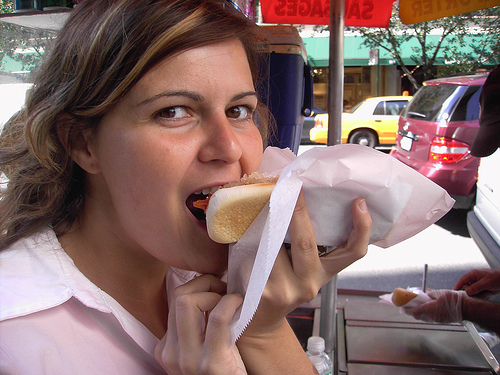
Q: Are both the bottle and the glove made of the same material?
A: Yes, both the bottle and the glove are made of plastic.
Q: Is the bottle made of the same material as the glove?
A: Yes, both the bottle and the glove are made of plastic.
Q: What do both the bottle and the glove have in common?
A: The material, both the bottle and the glove are plastic.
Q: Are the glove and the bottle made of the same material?
A: Yes, both the glove and the bottle are made of plastic.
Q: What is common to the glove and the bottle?
A: The material, both the glove and the bottle are plastic.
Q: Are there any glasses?
A: No, there are no glasses.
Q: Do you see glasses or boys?
A: No, there are no glasses or boys.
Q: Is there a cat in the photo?
A: No, there are no cats.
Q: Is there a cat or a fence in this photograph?
A: No, there are no cats or fences.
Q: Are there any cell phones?
A: No, there are no cell phones.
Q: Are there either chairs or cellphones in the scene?
A: No, there are no cellphones or chairs.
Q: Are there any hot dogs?
A: Yes, there is a hot dog.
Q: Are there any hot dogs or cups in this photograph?
A: Yes, there is a hot dog.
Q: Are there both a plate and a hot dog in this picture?
A: No, there is a hot dog but no plates.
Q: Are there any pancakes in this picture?
A: No, there are no pancakes.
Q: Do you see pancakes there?
A: No, there are no pancakes.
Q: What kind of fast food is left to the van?
A: The food is a hot dog.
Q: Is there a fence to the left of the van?
A: No, there is a hot dog to the left of the van.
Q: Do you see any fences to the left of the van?
A: No, there is a hot dog to the left of the van.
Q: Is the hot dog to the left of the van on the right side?
A: Yes, the hot dog is to the left of the van.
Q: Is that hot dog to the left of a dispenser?
A: No, the hot dog is to the left of the van.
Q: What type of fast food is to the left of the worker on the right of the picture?
A: The food is a hot dog.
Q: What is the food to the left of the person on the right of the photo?
A: The food is a hot dog.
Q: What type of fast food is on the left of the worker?
A: The food is a hot dog.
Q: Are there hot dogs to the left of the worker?
A: Yes, there is a hot dog to the left of the worker.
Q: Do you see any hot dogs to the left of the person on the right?
A: Yes, there is a hot dog to the left of the worker.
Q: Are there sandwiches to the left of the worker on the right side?
A: No, there is a hot dog to the left of the worker.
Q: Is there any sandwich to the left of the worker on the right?
A: No, there is a hot dog to the left of the worker.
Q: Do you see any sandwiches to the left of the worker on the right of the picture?
A: No, there is a hot dog to the left of the worker.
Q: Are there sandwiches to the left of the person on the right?
A: No, there is a hot dog to the left of the worker.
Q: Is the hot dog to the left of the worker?
A: Yes, the hot dog is to the left of the worker.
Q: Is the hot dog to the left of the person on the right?
A: Yes, the hot dog is to the left of the worker.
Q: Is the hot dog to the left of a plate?
A: No, the hot dog is to the left of the worker.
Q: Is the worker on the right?
A: Yes, the worker is on the right of the image.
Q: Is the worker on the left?
A: No, the worker is on the right of the image.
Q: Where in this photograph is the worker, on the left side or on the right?
A: The worker is on the right of the image.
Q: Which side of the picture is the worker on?
A: The worker is on the right of the image.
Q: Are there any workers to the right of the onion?
A: Yes, there is a worker to the right of the onion.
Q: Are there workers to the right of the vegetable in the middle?
A: Yes, there is a worker to the right of the onion.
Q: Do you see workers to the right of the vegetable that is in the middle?
A: Yes, there is a worker to the right of the onion.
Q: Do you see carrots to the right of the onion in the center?
A: No, there is a worker to the right of the onion.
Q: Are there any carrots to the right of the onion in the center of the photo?
A: No, there is a worker to the right of the onion.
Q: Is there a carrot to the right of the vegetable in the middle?
A: No, there is a worker to the right of the onion.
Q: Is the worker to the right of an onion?
A: Yes, the worker is to the right of an onion.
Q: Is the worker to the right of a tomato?
A: No, the worker is to the right of an onion.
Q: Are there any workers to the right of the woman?
A: Yes, there is a worker to the right of the woman.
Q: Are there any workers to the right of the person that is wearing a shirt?
A: Yes, there is a worker to the right of the woman.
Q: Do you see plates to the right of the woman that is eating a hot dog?
A: No, there is a worker to the right of the woman.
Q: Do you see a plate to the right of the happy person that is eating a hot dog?
A: No, there is a worker to the right of the woman.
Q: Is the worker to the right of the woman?
A: Yes, the worker is to the right of the woman.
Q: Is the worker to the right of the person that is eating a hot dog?
A: Yes, the worker is to the right of the woman.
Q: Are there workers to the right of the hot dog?
A: Yes, there is a worker to the right of the hot dog.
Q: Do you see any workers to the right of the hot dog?
A: Yes, there is a worker to the right of the hot dog.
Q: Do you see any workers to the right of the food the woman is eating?
A: Yes, there is a worker to the right of the hot dog.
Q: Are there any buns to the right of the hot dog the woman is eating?
A: No, there is a worker to the right of the hot dog.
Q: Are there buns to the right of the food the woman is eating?
A: No, there is a worker to the right of the hot dog.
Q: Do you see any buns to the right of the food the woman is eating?
A: No, there is a worker to the right of the hot dog.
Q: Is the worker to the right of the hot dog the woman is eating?
A: Yes, the worker is to the right of the hot dog.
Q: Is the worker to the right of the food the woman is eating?
A: Yes, the worker is to the right of the hot dog.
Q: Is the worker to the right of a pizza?
A: No, the worker is to the right of the hot dog.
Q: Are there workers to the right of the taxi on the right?
A: Yes, there is a worker to the right of the cab.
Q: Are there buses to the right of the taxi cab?
A: No, there is a worker to the right of the taxi cab.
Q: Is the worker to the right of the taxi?
A: Yes, the worker is to the right of the taxi.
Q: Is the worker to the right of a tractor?
A: No, the worker is to the right of the taxi.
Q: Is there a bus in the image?
A: No, there are no buses.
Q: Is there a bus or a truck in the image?
A: No, there are no buses or trucks.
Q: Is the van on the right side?
A: Yes, the van is on the right of the image.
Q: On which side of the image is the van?
A: The van is on the right of the image.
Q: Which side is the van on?
A: The van is on the right of the image.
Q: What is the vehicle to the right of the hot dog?
A: The vehicle is a van.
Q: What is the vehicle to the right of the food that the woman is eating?
A: The vehicle is a van.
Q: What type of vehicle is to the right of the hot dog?
A: The vehicle is a van.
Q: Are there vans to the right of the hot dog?
A: Yes, there is a van to the right of the hot dog.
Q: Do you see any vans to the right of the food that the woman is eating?
A: Yes, there is a van to the right of the hot dog.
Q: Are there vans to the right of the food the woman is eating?
A: Yes, there is a van to the right of the hot dog.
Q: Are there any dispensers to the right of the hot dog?
A: No, there is a van to the right of the hot dog.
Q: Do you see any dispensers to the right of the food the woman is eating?
A: No, there is a van to the right of the hot dog.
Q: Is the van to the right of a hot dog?
A: Yes, the van is to the right of a hot dog.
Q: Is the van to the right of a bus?
A: No, the van is to the right of a hot dog.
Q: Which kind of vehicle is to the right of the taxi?
A: The vehicle is a van.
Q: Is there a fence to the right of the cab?
A: No, there is a van to the right of the cab.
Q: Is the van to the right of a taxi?
A: Yes, the van is to the right of a taxi.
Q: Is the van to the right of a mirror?
A: No, the van is to the right of a taxi.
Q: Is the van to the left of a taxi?
A: No, the van is to the right of a taxi.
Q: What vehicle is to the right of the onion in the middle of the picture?
A: The vehicle is a van.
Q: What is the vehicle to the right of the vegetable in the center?
A: The vehicle is a van.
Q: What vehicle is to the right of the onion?
A: The vehicle is a van.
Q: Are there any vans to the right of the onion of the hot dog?
A: Yes, there is a van to the right of the onion.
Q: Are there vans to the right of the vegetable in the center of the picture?
A: Yes, there is a van to the right of the onion.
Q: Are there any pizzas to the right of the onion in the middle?
A: No, there is a van to the right of the onion.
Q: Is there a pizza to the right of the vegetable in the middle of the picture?
A: No, there is a van to the right of the onion.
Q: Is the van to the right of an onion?
A: Yes, the van is to the right of an onion.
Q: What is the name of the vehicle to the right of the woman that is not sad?
A: The vehicle is a van.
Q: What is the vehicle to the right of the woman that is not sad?
A: The vehicle is a van.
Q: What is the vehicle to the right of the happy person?
A: The vehicle is a van.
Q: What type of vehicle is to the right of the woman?
A: The vehicle is a van.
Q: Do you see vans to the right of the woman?
A: Yes, there is a van to the right of the woman.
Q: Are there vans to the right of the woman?
A: Yes, there is a van to the right of the woman.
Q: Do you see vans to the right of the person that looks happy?
A: Yes, there is a van to the right of the woman.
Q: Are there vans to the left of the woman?
A: No, the van is to the right of the woman.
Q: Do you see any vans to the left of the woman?
A: No, the van is to the right of the woman.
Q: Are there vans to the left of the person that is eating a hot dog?
A: No, the van is to the right of the woman.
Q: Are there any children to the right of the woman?
A: No, there is a van to the right of the woman.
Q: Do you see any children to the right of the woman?
A: No, there is a van to the right of the woman.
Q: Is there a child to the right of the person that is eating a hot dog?
A: No, there is a van to the right of the woman.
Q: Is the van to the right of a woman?
A: Yes, the van is to the right of a woman.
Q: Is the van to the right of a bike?
A: No, the van is to the right of a woman.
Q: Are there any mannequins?
A: No, there are no mannequins.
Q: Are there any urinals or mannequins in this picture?
A: No, there are no mannequins or urinals.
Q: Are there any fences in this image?
A: No, there are no fences.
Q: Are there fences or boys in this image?
A: No, there are no fences or boys.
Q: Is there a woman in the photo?
A: Yes, there is a woman.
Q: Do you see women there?
A: Yes, there is a woman.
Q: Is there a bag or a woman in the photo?
A: Yes, there is a woman.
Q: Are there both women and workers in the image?
A: Yes, there are both a woman and a worker.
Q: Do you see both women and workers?
A: Yes, there are both a woman and a worker.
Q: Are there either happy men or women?
A: Yes, there is a happy woman.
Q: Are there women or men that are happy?
A: Yes, the woman is happy.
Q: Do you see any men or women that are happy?
A: Yes, the woman is happy.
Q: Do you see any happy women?
A: Yes, there is a happy woman.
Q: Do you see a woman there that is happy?
A: Yes, there is a woman that is happy.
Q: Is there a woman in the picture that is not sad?
A: Yes, there is a happy woman.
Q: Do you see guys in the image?
A: No, there are no guys.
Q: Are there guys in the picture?
A: No, there are no guys.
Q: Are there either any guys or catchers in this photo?
A: No, there are no guys or catchers.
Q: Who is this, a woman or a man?
A: This is a woman.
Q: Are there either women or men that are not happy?
A: No, there is a woman but she is happy.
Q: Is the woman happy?
A: Yes, the woman is happy.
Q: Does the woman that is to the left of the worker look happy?
A: Yes, the woman is happy.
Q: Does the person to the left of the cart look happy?
A: Yes, the woman is happy.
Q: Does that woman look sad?
A: No, the woman is happy.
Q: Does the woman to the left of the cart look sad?
A: No, the woman is happy.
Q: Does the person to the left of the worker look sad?
A: No, the woman is happy.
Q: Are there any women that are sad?
A: No, there is a woman but she is happy.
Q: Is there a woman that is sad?
A: No, there is a woman but she is happy.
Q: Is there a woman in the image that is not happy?
A: No, there is a woman but she is happy.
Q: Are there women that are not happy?
A: No, there is a woman but she is happy.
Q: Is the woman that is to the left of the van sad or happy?
A: The woman is happy.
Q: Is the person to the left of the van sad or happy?
A: The woman is happy.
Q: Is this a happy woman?
A: Yes, this is a happy woman.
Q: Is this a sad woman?
A: No, this is a happy woman.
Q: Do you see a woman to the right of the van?
A: No, the woman is to the left of the van.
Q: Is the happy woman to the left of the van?
A: Yes, the woman is to the left of the van.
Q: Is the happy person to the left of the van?
A: Yes, the woman is to the left of the van.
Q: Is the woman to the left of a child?
A: No, the woman is to the left of the van.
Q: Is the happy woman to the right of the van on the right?
A: No, the woman is to the left of the van.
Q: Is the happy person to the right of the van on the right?
A: No, the woman is to the left of the van.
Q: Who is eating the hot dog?
A: The woman is eating the hot dog.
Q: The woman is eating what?
A: The woman is eating a hot dog.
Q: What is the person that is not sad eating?
A: The woman is eating a hot dog.